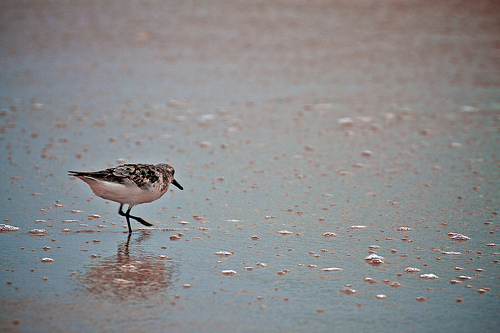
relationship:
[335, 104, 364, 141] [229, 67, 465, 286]
bubble on surface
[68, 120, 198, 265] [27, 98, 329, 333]
bird on ground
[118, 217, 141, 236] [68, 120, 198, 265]
leg of bird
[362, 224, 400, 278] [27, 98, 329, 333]
object on ground